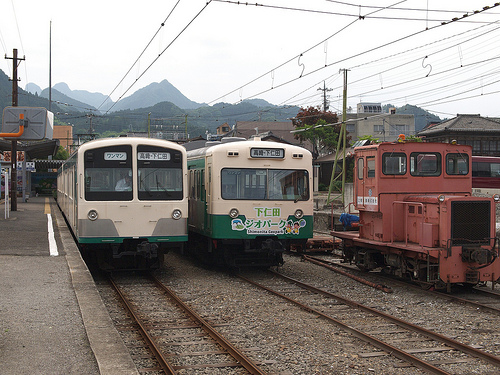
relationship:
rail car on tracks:
[51, 132, 192, 272] [101, 274, 218, 364]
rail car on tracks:
[186, 137, 320, 267] [124, 259, 481, 369]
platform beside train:
[2, 187, 144, 374] [54, 124, 191, 269]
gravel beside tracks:
[182, 274, 350, 374] [234, 267, 499, 373]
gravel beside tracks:
[182, 274, 350, 374] [99, 262, 259, 373]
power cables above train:
[112, 2, 484, 87] [55, 120, 185, 247]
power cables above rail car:
[112, 2, 484, 87] [186, 137, 320, 267]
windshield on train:
[87, 165, 182, 192] [66, 133, 194, 243]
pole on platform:
[7, 41, 29, 211] [2, 187, 144, 374]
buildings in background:
[248, 83, 496, 208] [0, 15, 481, 135]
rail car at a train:
[186, 137, 320, 267] [54, 124, 191, 269]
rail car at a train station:
[186, 137, 320, 267] [1, 99, 481, 360]